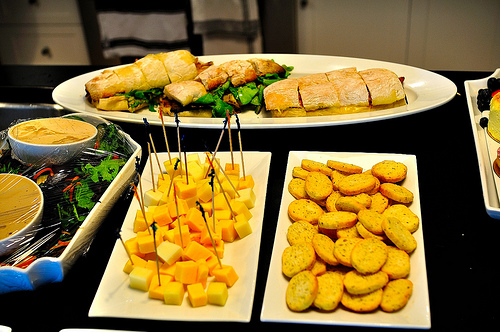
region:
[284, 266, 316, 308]
The bread is round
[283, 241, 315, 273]
The bread is round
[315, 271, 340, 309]
The bread is round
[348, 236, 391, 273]
The bread is round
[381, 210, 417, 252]
The bread is round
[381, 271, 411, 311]
The bread is round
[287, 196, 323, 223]
The bread is round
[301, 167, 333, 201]
The bread is round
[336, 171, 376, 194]
The bread is round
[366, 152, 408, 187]
The bread is round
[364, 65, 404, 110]
sandwich segment on plate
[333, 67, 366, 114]
sandwich segment on plate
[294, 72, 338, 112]
sandwich segment on plate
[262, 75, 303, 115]
sandwich segment on plate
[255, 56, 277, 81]
sandwich segment on plate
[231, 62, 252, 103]
sandwich segment on plate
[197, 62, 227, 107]
sandwich segment on plate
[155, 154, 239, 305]
cheese cubes on plate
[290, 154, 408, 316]
snacks on a plate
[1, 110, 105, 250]
salad on a plate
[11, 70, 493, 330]
a black table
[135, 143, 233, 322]
cheese on a plate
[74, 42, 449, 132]
a large white plate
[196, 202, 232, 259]
a tooth pick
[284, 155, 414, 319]
a plate of crackers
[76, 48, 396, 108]
a plate of sandwiches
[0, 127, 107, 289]
a bowl of salad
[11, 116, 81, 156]
a bowl of salad dressing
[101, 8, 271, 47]
towels hanging from the stove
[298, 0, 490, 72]
white cabinets behind the table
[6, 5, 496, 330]
an island in a kitchen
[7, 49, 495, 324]
h'orderves are on the counter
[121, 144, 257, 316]
toothpicks are in the cheese cubes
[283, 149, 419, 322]
crusty bread rounds are on a plate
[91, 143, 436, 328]
the oblong serving trays are white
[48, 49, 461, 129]
the oval serving tray is white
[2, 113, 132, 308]
plastic is covering the dishes of hummus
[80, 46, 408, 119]
sandwiches are on the tray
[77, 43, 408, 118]
the sandwiches have been sliced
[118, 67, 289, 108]
the sandwiches have green leaves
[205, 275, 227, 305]
The cheese is cubed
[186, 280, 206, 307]
The cheese is cubed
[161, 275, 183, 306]
The cheese is cubed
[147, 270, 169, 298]
The cheese is cubed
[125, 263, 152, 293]
The cheese is cubed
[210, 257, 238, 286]
The cheese is cubed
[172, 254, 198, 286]
The cheese is cubed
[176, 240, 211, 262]
The cheese is cubed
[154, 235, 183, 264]
The cheese is cubed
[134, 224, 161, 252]
The cheese is cubed